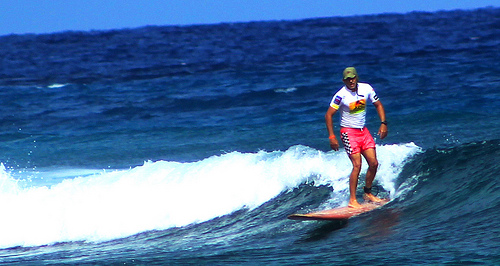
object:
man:
[324, 66, 389, 210]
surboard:
[289, 200, 392, 229]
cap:
[340, 67, 358, 80]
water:
[0, 7, 500, 265]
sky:
[0, 0, 498, 37]